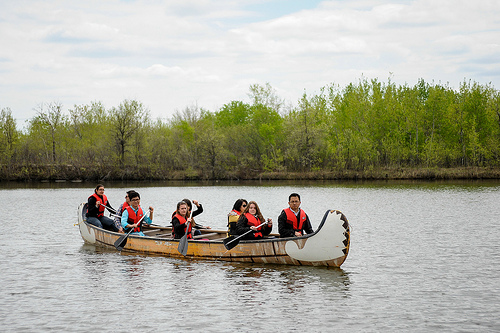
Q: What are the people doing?
A: Canoeing.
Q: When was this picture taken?
A: Daytime.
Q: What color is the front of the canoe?
A: White.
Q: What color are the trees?
A: Green.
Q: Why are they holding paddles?
A: To paddle the boat.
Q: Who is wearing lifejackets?
A: People in the canoe.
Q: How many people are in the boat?
A: 8.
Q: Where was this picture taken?
A: Outside in the open air.